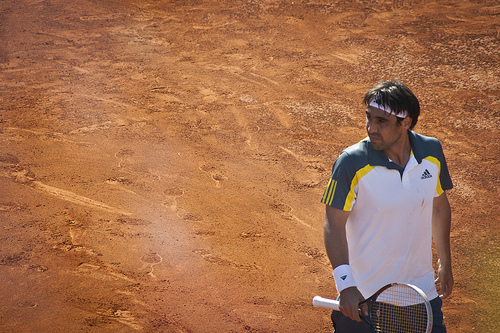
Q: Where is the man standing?
A: Tennis court.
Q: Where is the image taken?
A: On ground.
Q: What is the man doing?
A: Playing tennis.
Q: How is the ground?
A: Reddish brown.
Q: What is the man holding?
A: Racket.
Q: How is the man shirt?
A: Mostly white.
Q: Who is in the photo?
A: A man.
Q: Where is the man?
A: Outside somewhere.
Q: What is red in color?
A: The ground.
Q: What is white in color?
A: The shirt.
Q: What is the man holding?
A: A racket.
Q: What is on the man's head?
A: Headband.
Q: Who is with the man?
A: No people.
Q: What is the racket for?
A: Tennis.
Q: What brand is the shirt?
A: Adidas.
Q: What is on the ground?
A: Tracks.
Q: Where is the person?
A: In the desert.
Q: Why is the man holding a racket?
A: He is playing tennis.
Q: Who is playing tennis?
A: The man.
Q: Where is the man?
A: On a field.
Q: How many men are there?
A: One.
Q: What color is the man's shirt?
A: White.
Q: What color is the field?
A: Orange.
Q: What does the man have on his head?
A: A sweatband.